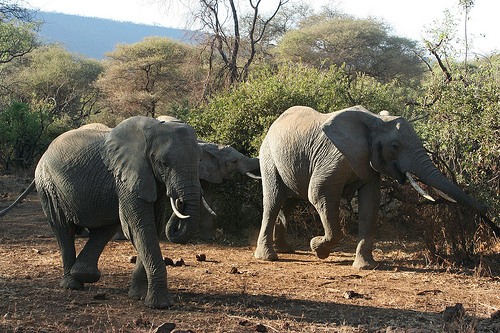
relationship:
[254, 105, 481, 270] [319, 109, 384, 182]
elephant has ear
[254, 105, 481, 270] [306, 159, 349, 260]
elephant has front right foot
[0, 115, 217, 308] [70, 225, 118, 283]
elephant has back left foot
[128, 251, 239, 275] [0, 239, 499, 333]
elephant dung on ground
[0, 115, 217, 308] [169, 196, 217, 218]
elephant has tusks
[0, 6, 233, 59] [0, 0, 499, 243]
mountain behind trees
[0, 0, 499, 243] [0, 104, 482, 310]
trees behind three elephants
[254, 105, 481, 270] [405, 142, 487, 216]
elephant has trunk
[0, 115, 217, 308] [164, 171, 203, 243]
elephant has trunk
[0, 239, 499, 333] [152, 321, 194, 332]
ground has rocks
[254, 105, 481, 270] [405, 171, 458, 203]
elephant has tusks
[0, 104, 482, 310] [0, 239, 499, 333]
three elephants walking on ground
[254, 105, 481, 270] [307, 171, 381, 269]
elephant has front legs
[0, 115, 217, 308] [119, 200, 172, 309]
elephant has front legs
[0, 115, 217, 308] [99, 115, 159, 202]
elephant has ear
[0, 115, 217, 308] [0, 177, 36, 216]
elephant has tail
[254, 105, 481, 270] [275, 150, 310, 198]
elephant has stomach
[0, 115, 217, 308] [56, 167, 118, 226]
elephant has stomach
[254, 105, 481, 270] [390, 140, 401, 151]
elephant has eye